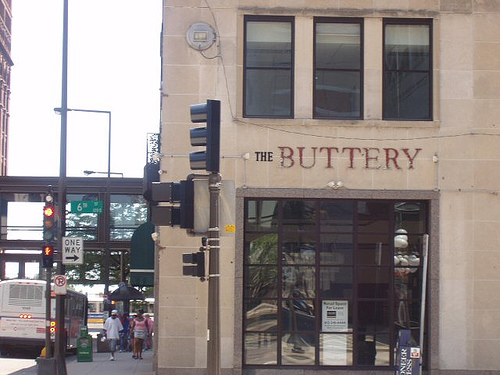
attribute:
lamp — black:
[166, 109, 246, 364]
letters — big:
[275, 142, 437, 179]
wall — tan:
[160, 2, 243, 373]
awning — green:
[130, 220, 152, 287]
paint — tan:
[153, 2, 497, 372]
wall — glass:
[148, 1, 498, 373]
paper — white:
[320, 295, 348, 331]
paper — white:
[319, 330, 349, 367]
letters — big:
[276, 143, 422, 171]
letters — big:
[250, 141, 422, 176]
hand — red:
[44, 223, 97, 282]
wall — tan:
[160, 4, 497, 351]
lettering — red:
[280, 141, 422, 173]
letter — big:
[280, 144, 425, 179]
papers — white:
[322, 294, 354, 365]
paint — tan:
[175, 345, 188, 358]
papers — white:
[294, 286, 406, 354]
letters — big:
[238, 126, 448, 189]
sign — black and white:
[62, 238, 82, 263]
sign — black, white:
[317, 299, 350, 334]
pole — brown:
[185, 168, 255, 372]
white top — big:
[102, 317, 122, 339]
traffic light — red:
[187, 96, 221, 172]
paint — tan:
[450, 164, 484, 177]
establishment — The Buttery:
[160, 0, 494, 375]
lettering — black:
[254, 149, 274, 163]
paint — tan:
[459, 155, 484, 268]